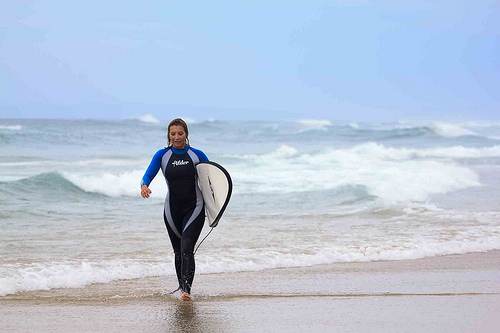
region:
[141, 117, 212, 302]
Woman walking out of the water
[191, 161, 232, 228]
Surfboard woman is carrying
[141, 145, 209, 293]
Blue surfing outfit woman is wearing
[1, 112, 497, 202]
Waves in back of the woman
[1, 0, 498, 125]
clear blue sky above the ocean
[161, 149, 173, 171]
White strip on upper right shoulder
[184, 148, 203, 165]
Upper left shoulder with a white strip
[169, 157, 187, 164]
White print on the front of top woman is wearing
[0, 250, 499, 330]
Sandy beach woman is walking on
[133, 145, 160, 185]
Right arm of the woman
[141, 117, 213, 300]
a woman walking on the beach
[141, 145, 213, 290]
woman wearing a wet suit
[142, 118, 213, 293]
woman wet from being in the ocean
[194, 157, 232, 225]
a black and white surfboard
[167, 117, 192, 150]
woman with wet hair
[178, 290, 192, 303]
woman walking barefoot on the beach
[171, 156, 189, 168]
a white logo on a wet suit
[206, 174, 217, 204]
a black logo on a surfboard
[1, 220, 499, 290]
a wash washing gently on the sand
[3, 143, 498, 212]
a wave crashing in the ocean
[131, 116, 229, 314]
woman walking on sand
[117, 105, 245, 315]
woman walking on the beach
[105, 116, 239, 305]
woman in the ocean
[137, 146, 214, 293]
wetsuit on top of woman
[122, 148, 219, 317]
black wetsuit on woman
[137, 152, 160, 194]
blue arms to wet suit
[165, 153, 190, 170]
logo on front of wet suit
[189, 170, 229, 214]
bottom of surf board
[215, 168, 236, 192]
black edge of surf board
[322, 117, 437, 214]
white water and waves in ocean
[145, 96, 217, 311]
a woman walking out of the ocean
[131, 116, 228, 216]
the woman is carrying a surfboard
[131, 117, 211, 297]
the woman is wearing a wet suit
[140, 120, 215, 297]
the wet suit has three colors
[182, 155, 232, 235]
the woman's surfboard is white with black trim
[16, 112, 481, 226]
the ocean is in the background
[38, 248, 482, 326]
the sand is under the woman's feet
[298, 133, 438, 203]
water is splashing in the ocean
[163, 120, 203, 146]
the woman's hair is down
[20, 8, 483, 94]
the sky is blue in color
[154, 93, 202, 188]
the head of a woman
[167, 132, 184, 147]
the nose of a woman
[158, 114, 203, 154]
the hair of a woman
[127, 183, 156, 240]
the hand of a woman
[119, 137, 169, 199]
the arm of a woman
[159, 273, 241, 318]
the foot of a woman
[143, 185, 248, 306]
the legs of a woman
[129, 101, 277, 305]
a woman wearing a wet suit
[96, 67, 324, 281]
a woman holding a surfboard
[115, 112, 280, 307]
a woman on the sand